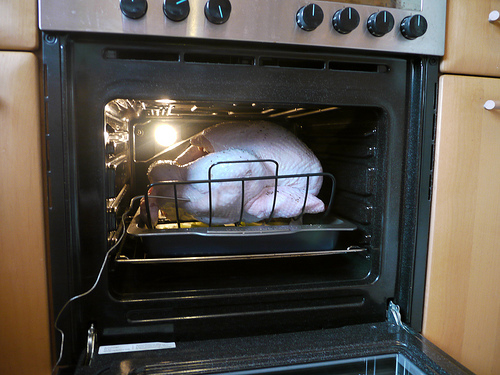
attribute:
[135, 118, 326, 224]
turkey — uncooked, raw, unstuffed, sitting, baking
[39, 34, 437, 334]
oven — black, open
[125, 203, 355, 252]
pan — roasting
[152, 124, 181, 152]
light — on, glowing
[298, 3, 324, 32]
knob — black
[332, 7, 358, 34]
knob — black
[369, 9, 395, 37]
knob — set, round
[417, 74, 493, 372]
cabinet — wooden, light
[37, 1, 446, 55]
control panel — silver, stainless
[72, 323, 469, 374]
door — open, shiny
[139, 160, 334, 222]
rack — shiny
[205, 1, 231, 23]
knob — black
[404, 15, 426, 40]
knob — black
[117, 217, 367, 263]
rack — black